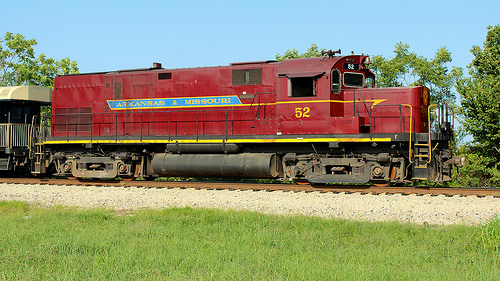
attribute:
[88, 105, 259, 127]
pain — red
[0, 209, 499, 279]
grass — healthy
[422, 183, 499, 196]
tracks — brown steel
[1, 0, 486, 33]
blue sky — clear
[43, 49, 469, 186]
train — red